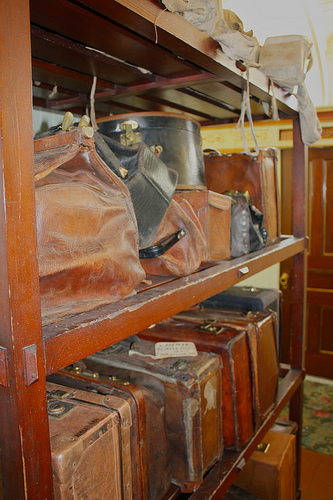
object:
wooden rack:
[0, 0, 311, 499]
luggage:
[32, 105, 149, 316]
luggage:
[45, 375, 135, 499]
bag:
[253, 31, 314, 126]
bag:
[210, 1, 263, 163]